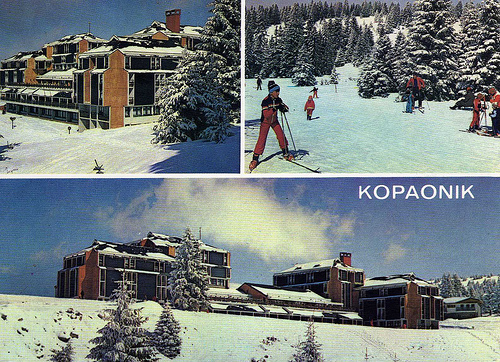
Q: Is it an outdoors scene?
A: Yes, it is outdoors.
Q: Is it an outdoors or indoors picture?
A: It is outdoors.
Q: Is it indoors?
A: No, it is outdoors.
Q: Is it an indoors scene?
A: No, it is outdoors.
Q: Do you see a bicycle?
A: No, there are no bicycles.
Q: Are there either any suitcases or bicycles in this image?
A: No, there are no bicycles or suitcases.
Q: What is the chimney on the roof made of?
A: The chimney is made of brick.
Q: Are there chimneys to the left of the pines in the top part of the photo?
A: Yes, there is a chimney to the left of the pines.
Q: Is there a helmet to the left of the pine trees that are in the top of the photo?
A: No, there is a chimney to the left of the pine trees.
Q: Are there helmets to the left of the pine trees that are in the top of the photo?
A: No, there is a chimney to the left of the pine trees.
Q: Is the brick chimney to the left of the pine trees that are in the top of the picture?
A: Yes, the chimney is to the left of the pines.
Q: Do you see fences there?
A: No, there are no fences.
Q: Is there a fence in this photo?
A: No, there are no fences.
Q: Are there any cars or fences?
A: No, there are no fences or cars.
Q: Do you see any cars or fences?
A: No, there are no fences or cars.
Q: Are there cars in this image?
A: No, there are no cars.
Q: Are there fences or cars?
A: No, there are no cars or fences.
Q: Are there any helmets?
A: No, there are no helmets.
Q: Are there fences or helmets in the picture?
A: No, there are no helmets or fences.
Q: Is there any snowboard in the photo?
A: No, there are no snowboards.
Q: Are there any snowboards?
A: No, there are no snowboards.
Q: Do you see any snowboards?
A: No, there are no snowboards.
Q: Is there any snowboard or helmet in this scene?
A: No, there are no snowboards or helmets.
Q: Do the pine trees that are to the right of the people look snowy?
A: Yes, the pines are snowy.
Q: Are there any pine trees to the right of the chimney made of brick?
A: Yes, there are pine trees to the right of the chimney.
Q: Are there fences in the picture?
A: No, there are no fences.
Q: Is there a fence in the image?
A: No, there are no fences.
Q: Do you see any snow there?
A: Yes, there is snow.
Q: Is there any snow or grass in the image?
A: Yes, there is snow.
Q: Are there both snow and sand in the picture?
A: No, there is snow but no sand.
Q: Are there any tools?
A: No, there are no tools.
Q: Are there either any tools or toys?
A: No, there are no tools or toys.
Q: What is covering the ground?
A: The snow is covering the ground.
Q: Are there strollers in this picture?
A: No, there are no strollers.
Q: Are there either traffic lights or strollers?
A: No, there are no strollers or traffic lights.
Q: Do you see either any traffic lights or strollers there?
A: No, there are no strollers or traffic lights.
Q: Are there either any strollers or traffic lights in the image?
A: No, there are no strollers or traffic lights.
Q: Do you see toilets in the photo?
A: No, there are no toilets.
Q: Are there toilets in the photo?
A: No, there are no toilets.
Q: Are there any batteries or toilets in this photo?
A: No, there are no toilets or batteries.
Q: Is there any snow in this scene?
A: Yes, there is snow.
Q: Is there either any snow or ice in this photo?
A: Yes, there is snow.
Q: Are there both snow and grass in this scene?
A: No, there is snow but no grass.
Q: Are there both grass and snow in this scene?
A: No, there is snow but no grass.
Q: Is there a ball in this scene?
A: No, there are no balls.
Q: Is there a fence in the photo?
A: No, there are no fences.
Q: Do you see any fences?
A: No, there are no fences.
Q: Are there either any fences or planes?
A: No, there are no fences or planes.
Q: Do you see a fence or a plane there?
A: No, there are no fences or airplanes.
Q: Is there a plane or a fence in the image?
A: No, there are no fences or airplanes.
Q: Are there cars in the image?
A: No, there are no cars.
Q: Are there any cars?
A: No, there are no cars.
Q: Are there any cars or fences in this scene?
A: No, there are no cars or fences.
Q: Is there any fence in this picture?
A: No, there are no fences.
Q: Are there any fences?
A: No, there are no fences.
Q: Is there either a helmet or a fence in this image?
A: No, there are no fences or helmets.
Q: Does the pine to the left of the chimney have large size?
A: Yes, the pine is large.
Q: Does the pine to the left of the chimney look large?
A: Yes, the pine is large.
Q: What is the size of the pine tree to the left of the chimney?
A: The pine is large.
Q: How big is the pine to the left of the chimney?
A: The pine is large.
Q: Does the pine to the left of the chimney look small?
A: No, the pine is large.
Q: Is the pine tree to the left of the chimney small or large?
A: The pine tree is large.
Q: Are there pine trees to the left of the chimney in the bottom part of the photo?
A: Yes, there is a pine tree to the left of the chimney.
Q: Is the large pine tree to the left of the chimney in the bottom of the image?
A: Yes, the pine tree is to the left of the chimney.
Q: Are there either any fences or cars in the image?
A: No, there are no fences or cars.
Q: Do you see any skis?
A: Yes, there are skis.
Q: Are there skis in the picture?
A: Yes, there are skis.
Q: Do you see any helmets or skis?
A: Yes, there are skis.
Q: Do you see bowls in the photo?
A: No, there are no bowls.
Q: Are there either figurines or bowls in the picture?
A: No, there are no bowls or figurines.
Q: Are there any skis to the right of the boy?
A: Yes, there are skis to the right of the boy.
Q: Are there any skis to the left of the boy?
A: No, the skis are to the right of the boy.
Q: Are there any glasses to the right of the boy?
A: No, there are skis to the right of the boy.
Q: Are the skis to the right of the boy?
A: Yes, the skis are to the right of the boy.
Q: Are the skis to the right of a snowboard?
A: No, the skis are to the right of the boy.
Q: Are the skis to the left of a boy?
A: No, the skis are to the right of a boy.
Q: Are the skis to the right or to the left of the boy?
A: The skis are to the right of the boy.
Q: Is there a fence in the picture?
A: No, there are no fences.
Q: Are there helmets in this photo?
A: No, there are no helmets.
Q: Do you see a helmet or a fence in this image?
A: No, there are no helmets or fences.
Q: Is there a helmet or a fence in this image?
A: No, there are no helmets or fences.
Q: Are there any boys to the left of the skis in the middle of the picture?
A: Yes, there is a boy to the left of the skis.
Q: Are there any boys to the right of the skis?
A: No, the boy is to the left of the skis.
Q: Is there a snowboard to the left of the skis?
A: No, there is a boy to the left of the skis.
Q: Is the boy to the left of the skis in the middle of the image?
A: Yes, the boy is to the left of the skis.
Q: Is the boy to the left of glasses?
A: No, the boy is to the left of the skis.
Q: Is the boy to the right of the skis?
A: No, the boy is to the left of the skis.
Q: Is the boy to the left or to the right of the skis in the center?
A: The boy is to the left of the skis.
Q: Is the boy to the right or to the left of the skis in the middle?
A: The boy is to the left of the skis.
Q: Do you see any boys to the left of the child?
A: Yes, there is a boy to the left of the child.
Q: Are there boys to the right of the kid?
A: No, the boy is to the left of the kid.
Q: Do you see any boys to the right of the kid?
A: No, the boy is to the left of the kid.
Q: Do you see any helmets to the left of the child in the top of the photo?
A: No, there is a boy to the left of the kid.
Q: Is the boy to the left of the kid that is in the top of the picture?
A: Yes, the boy is to the left of the child.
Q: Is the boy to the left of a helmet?
A: No, the boy is to the left of the child.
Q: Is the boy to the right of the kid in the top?
A: No, the boy is to the left of the kid.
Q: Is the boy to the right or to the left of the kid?
A: The boy is to the left of the kid.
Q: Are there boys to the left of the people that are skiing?
A: Yes, there is a boy to the left of the people.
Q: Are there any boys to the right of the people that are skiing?
A: No, the boy is to the left of the people.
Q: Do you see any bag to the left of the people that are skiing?
A: No, there is a boy to the left of the people.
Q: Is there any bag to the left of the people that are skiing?
A: No, there is a boy to the left of the people.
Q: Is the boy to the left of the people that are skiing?
A: Yes, the boy is to the left of the people.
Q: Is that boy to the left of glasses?
A: No, the boy is to the left of the people.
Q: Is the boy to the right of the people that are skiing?
A: No, the boy is to the left of the people.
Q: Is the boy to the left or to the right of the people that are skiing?
A: The boy is to the left of the people.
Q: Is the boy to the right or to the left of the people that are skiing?
A: The boy is to the left of the people.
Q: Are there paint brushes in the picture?
A: No, there are no paint brushes.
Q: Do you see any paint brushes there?
A: No, there are no paint brushes.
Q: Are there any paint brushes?
A: No, there are no paint brushes.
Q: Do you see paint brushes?
A: No, there are no paint brushes.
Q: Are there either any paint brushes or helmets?
A: No, there are no paint brushes or helmets.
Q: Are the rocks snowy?
A: Yes, the rocks are snowy.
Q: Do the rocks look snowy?
A: Yes, the rocks are snowy.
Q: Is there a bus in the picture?
A: No, there are no buses.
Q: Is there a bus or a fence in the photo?
A: No, there are no buses or fences.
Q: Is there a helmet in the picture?
A: No, there are no helmets.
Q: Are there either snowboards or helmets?
A: No, there are no helmets or snowboards.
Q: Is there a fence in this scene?
A: No, there are no fences.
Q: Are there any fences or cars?
A: No, there are no fences or cars.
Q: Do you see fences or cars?
A: No, there are no fences or cars.